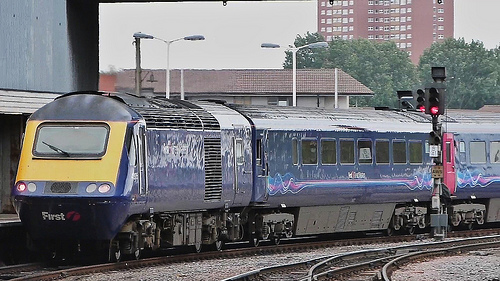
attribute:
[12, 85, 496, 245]
train — yellow, blue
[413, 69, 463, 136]
light — red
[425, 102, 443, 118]
light — red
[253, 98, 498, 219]
train — blue